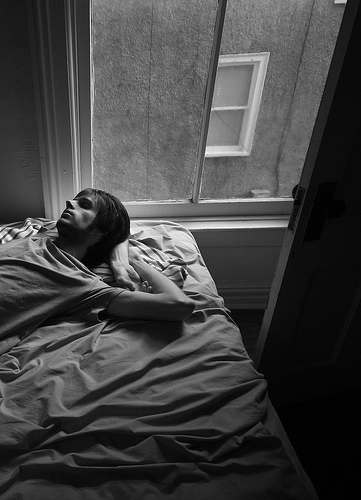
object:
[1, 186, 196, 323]
guy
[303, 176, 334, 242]
handle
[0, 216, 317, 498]
sheets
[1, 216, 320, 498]
bed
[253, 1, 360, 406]
door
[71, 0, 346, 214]
window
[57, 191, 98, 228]
face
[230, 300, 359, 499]
floor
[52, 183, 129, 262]
head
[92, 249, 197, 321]
arm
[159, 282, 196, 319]
elbow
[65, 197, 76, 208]
nose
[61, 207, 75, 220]
mouth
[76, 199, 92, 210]
eye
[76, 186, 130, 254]
hair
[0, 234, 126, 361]
shirt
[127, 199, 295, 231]
ledge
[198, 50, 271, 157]
window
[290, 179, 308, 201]
door knob